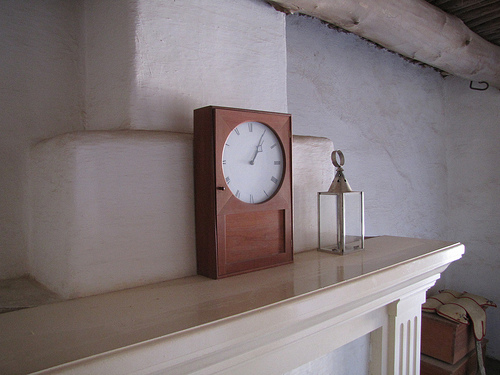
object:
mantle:
[1, 234, 459, 375]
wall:
[1, 2, 500, 363]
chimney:
[21, 0, 336, 299]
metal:
[317, 149, 365, 256]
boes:
[422, 289, 497, 341]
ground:
[292, 50, 449, 185]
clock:
[192, 105, 294, 280]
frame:
[193, 105, 292, 279]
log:
[266, 0, 498, 85]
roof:
[423, 0, 500, 45]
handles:
[250, 129, 266, 165]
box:
[419, 289, 488, 375]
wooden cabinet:
[192, 105, 294, 280]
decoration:
[317, 149, 365, 255]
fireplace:
[5, 235, 465, 375]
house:
[0, 0, 500, 375]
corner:
[423, 241, 479, 299]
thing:
[316, 150, 364, 255]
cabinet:
[193, 105, 295, 280]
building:
[0, 0, 500, 299]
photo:
[0, 0, 500, 375]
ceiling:
[420, 0, 500, 47]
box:
[317, 149, 365, 256]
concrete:
[362, 147, 458, 226]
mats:
[422, 286, 497, 340]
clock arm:
[253, 131, 266, 161]